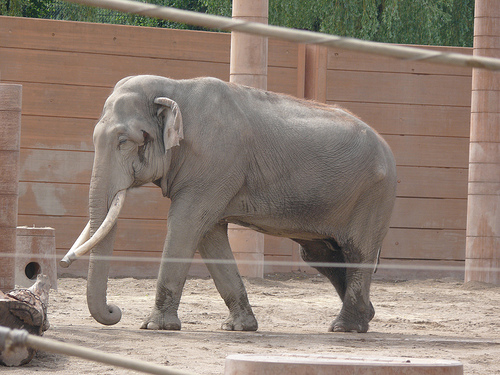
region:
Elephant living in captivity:
[0, 0, 498, 374]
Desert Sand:
[1, 263, 498, 373]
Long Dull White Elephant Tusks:
[55, 181, 142, 270]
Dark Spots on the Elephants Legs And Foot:
[290, 231, 376, 338]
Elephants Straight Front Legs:
[133, 205, 275, 336]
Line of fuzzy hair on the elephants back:
[240, 82, 369, 127]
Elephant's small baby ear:
[146, 93, 187, 161]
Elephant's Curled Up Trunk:
[82, 150, 128, 333]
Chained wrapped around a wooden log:
[5, 281, 57, 349]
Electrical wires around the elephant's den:
[5, 234, 497, 371]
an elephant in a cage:
[23, 9, 470, 364]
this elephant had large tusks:
[50, 171, 126, 277]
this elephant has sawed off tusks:
[50, 243, 81, 277]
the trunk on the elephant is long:
[55, 84, 156, 325]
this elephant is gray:
[62, 63, 404, 334]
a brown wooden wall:
[13, 20, 490, 273]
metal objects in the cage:
[9, 287, 207, 374]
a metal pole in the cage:
[136, 4, 488, 82]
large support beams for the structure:
[452, 4, 497, 297]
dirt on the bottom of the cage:
[74, 257, 481, 359]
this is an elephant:
[73, 85, 397, 311]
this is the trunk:
[85, 244, 121, 326]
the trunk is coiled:
[85, 275, 139, 325]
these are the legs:
[146, 232, 244, 330]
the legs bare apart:
[157, 232, 247, 335]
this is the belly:
[269, 122, 362, 205]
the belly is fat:
[268, 118, 360, 198]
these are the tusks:
[63, 229, 103, 265]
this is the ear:
[149, 91, 189, 139]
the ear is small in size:
[150, 95, 185, 146]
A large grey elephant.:
[62, 75, 399, 334]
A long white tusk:
[72, 191, 124, 256]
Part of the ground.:
[416, 303, 448, 343]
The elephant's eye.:
[113, 130, 133, 148]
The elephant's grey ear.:
[153, 92, 182, 154]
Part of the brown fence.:
[41, 103, 81, 135]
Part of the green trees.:
[383, 13, 439, 36]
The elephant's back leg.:
[328, 233, 370, 334]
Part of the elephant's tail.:
[374, 248, 381, 275]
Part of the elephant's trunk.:
[86, 258, 123, 325]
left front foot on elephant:
[135, 310, 193, 329]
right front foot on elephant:
[231, 279, 253, 349]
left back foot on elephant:
[338, 314, 365, 331]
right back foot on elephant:
[325, 275, 376, 320]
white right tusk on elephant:
[68, 222, 75, 263]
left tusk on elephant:
[83, 235, 110, 263]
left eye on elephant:
[117, 135, 154, 167]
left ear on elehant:
[151, 107, 209, 177]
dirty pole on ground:
[37, 322, 102, 369]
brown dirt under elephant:
[255, 265, 363, 352]